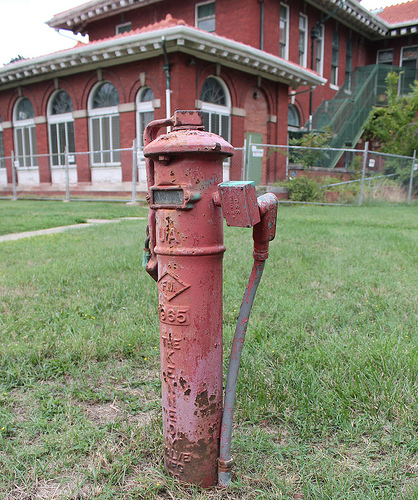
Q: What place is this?
A: It is a field.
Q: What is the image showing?
A: It is showing a field.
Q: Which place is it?
A: It is a field.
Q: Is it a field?
A: Yes, it is a field.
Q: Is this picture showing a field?
A: Yes, it is showing a field.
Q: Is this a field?
A: Yes, it is a field.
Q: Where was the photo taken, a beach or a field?
A: It was taken at a field.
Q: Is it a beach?
A: No, it is a field.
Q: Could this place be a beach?
A: No, it is a field.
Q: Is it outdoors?
A: Yes, it is outdoors.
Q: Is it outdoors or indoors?
A: It is outdoors.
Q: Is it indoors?
A: No, it is outdoors.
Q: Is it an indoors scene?
A: No, it is outdoors.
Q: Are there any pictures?
A: No, there are no pictures.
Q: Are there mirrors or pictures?
A: No, there are no pictures or mirrors.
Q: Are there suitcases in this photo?
A: No, there are no suitcases.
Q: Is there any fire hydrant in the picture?
A: Yes, there is a fire hydrant.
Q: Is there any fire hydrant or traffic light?
A: Yes, there is a fire hydrant.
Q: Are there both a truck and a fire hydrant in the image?
A: No, there is a fire hydrant but no trucks.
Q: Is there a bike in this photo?
A: No, there are no bikes.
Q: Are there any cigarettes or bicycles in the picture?
A: No, there are no bicycles or cigarettes.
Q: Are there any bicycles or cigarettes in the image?
A: No, there are no bicycles or cigarettes.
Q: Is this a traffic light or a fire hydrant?
A: This is a fire hydrant.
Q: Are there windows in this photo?
A: Yes, there is a window.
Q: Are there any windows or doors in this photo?
A: Yes, there is a window.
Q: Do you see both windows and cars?
A: No, there is a window but no cars.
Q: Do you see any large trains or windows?
A: Yes, there is a large window.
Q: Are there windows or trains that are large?
A: Yes, the window is large.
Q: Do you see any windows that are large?
A: Yes, there is a large window.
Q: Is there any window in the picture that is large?
A: Yes, there is a window that is large.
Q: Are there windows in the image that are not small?
A: Yes, there is a large window.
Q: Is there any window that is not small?
A: Yes, there is a large window.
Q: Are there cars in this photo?
A: No, there are no cars.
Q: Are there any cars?
A: No, there are no cars.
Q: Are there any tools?
A: No, there are no tools.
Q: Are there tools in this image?
A: No, there are no tools.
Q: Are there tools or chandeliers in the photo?
A: No, there are no tools or chandeliers.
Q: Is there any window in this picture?
A: Yes, there is a window.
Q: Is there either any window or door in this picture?
A: Yes, there is a window.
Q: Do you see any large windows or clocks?
A: Yes, there is a large window.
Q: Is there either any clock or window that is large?
A: Yes, the window is large.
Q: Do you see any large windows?
A: Yes, there is a large window.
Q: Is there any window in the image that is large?
A: Yes, there is a window that is large.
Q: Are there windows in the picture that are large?
A: Yes, there is a window that is large.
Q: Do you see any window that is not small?
A: Yes, there is a large window.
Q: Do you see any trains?
A: No, there are no trains.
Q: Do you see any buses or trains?
A: No, there are no trains or buses.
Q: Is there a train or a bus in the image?
A: No, there are no trains or buses.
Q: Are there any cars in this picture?
A: No, there are no cars.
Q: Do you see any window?
A: Yes, there is a window.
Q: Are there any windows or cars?
A: Yes, there is a window.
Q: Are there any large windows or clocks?
A: Yes, there is a large window.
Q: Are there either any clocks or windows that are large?
A: Yes, the window is large.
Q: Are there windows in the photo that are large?
A: Yes, there is a large window.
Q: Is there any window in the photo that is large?
A: Yes, there is a window that is large.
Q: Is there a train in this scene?
A: No, there are no trains.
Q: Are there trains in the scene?
A: No, there are no trains.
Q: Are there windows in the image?
A: Yes, there is a window.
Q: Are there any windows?
A: Yes, there is a window.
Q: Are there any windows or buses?
A: Yes, there is a window.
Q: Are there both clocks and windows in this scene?
A: No, there is a window but no clocks.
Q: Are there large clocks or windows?
A: Yes, there is a large window.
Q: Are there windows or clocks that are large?
A: Yes, the window is large.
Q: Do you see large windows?
A: Yes, there is a large window.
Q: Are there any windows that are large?
A: Yes, there is a window that is large.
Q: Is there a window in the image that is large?
A: Yes, there is a window that is large.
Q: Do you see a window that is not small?
A: Yes, there is a large window.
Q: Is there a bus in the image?
A: No, there are no buses.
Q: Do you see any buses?
A: No, there are no buses.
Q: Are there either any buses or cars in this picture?
A: No, there are no buses or cars.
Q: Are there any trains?
A: No, there are no trains.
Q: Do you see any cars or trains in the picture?
A: No, there are no trains or cars.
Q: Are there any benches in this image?
A: No, there are no benches.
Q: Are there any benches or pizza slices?
A: No, there are no benches or pizza slices.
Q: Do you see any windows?
A: Yes, there is a window.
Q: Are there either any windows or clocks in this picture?
A: Yes, there is a window.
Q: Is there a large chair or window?
A: Yes, there is a large window.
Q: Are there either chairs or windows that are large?
A: Yes, the window is large.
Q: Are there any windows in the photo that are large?
A: Yes, there is a large window.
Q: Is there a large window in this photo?
A: Yes, there is a large window.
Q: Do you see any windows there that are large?
A: Yes, there is a window that is large.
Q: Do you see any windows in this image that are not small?
A: Yes, there is a large window.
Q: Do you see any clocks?
A: No, there are no clocks.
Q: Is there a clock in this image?
A: No, there are no clocks.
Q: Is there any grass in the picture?
A: Yes, there is grass.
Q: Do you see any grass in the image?
A: Yes, there is grass.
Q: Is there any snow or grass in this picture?
A: Yes, there is grass.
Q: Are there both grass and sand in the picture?
A: No, there is grass but no sand.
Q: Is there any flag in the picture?
A: No, there are no flags.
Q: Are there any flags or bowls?
A: No, there are no flags or bowls.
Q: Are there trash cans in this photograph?
A: No, there are no trash cans.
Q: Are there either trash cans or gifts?
A: No, there are no trash cans or gifts.